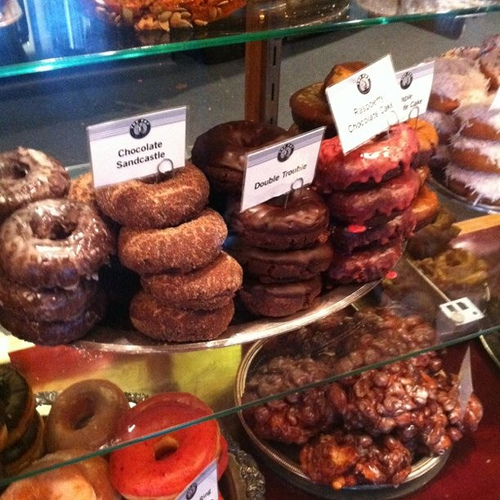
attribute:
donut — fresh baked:
[276, 313, 344, 369]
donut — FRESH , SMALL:
[33, 369, 138, 451]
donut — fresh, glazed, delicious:
[4, 205, 104, 272]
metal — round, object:
[221, 339, 496, 494]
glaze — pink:
[341, 131, 415, 179]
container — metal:
[118, 243, 448, 491]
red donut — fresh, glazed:
[331, 174, 421, 228]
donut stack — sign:
[193, 96, 421, 306]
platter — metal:
[0, 390, 268, 499]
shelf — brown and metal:
[3, 290, 491, 487]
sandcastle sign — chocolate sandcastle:
[88, 102, 186, 189]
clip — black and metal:
[141, 152, 176, 182]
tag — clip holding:
[243, 127, 338, 204]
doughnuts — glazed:
[97, 163, 212, 230]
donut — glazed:
[236, 277, 324, 318]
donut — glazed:
[231, 239, 336, 284]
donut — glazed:
[226, 192, 331, 252]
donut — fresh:
[1, 193, 121, 293]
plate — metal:
[75, 309, 412, 351]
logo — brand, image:
[277, 140, 297, 165]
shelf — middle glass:
[2, 250, 496, 484]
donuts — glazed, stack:
[313, 119, 404, 299]